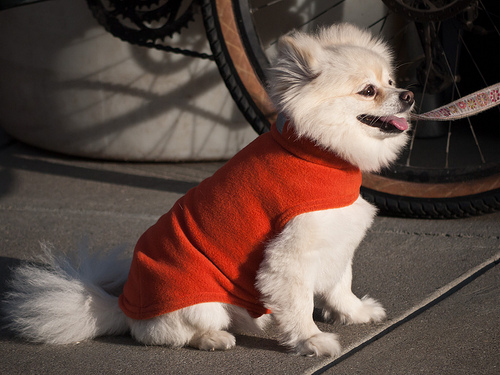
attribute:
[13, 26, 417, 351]
dog — small, white, groomed, easy, happy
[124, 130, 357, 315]
sweater — orange, red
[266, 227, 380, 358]
legs — white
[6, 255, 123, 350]
dog tail — white, puffy, fluffy, furry, bushy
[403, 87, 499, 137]
leash — flowered, floral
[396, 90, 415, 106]
nose — small, brown, black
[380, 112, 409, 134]
tongue — pink, out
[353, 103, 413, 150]
dog mouth — open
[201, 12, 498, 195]
tire — black, brown, spoke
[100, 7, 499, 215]
bike — parked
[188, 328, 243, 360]
right paw — back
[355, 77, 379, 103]
dogs eye — brown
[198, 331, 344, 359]
dogs paw — beige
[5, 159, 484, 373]
floor — grey, cement, smooth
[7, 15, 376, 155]
building — white